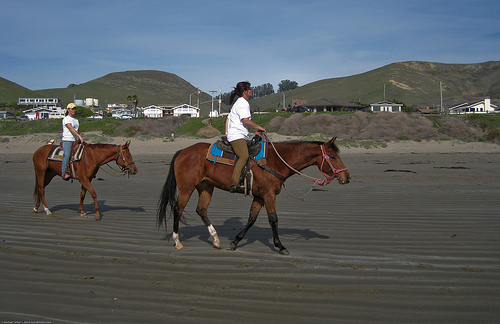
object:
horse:
[153, 132, 357, 257]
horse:
[27, 134, 140, 221]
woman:
[221, 80, 269, 193]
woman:
[59, 100, 85, 181]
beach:
[1, 151, 500, 324]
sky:
[1, 3, 500, 98]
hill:
[23, 60, 229, 115]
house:
[442, 96, 500, 118]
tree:
[276, 78, 301, 93]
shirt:
[222, 94, 256, 146]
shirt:
[58, 114, 85, 142]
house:
[368, 98, 407, 114]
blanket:
[45, 143, 87, 163]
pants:
[229, 137, 251, 193]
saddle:
[214, 131, 265, 160]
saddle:
[55, 137, 84, 156]